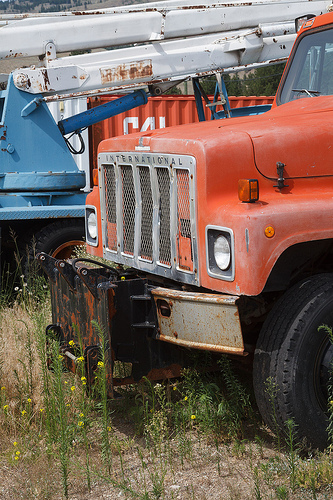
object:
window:
[96, 152, 197, 285]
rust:
[97, 57, 156, 88]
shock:
[59, 87, 147, 139]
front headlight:
[85, 205, 99, 247]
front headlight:
[205, 224, 234, 276]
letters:
[107, 156, 183, 167]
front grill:
[97, 148, 198, 286]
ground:
[0, 304, 331, 497]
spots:
[192, 295, 198, 300]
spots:
[166, 300, 172, 306]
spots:
[172, 331, 177, 337]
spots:
[234, 310, 238, 317]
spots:
[213, 313, 222, 318]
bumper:
[50, 254, 249, 399]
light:
[266, 226, 274, 237]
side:
[234, 112, 331, 454]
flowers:
[96, 360, 104, 369]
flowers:
[24, 396, 33, 402]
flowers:
[120, 275, 125, 280]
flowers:
[70, 384, 76, 391]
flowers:
[66, 338, 75, 345]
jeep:
[45, 13, 333, 454]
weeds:
[0, 346, 202, 484]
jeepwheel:
[257, 273, 331, 459]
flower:
[98, 361, 104, 368]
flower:
[69, 340, 76, 347]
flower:
[81, 375, 87, 384]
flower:
[77, 354, 86, 363]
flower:
[27, 397, 32, 402]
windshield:
[276, 26, 332, 104]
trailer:
[84, 92, 277, 189]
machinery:
[46, 258, 154, 398]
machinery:
[0, 8, 304, 83]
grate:
[91, 150, 203, 273]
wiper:
[290, 88, 321, 104]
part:
[58, 223, 242, 360]